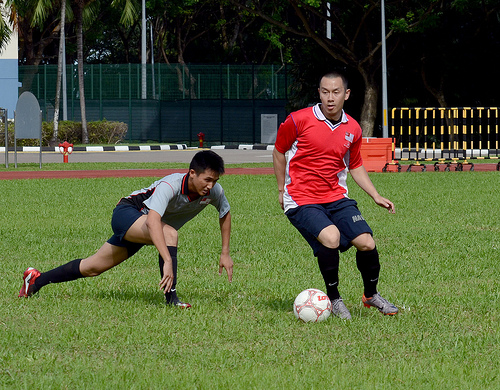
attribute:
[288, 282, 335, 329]
soccer ball — red, white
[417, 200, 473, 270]
grass — green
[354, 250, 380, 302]
socks — black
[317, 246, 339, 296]
socks — black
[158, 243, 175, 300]
socks — black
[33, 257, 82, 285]
socks — black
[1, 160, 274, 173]
grass —  green, patch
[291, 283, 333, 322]
ball — red, white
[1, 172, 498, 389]
grass —  patch,  green, patch, green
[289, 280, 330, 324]
ball — white, red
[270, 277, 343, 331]
ball — white, red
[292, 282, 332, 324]
soccer ball — white, red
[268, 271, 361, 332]
ball — soccer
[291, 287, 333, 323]
ball — red, white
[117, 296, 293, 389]
grass — green, patch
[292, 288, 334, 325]
soccer ball — white, red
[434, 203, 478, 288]
grass —  patch,  green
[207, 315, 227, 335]
grass — green